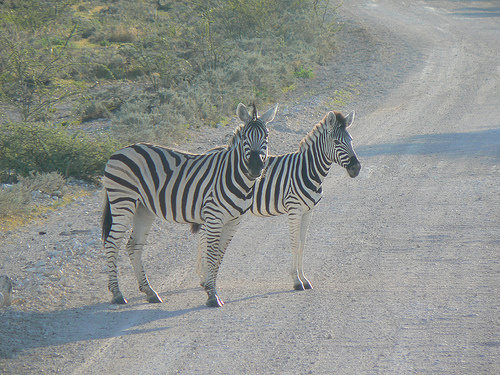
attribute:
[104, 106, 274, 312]
zebra — black, white, striped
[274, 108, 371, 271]
zebra — black, white, striped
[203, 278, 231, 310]
hoofs — black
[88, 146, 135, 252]
hind quarters — black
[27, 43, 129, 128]
leaves — green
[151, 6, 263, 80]
plants — green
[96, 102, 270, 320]
zebra — white, black, striped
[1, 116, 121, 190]
bush — green, small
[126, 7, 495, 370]
road — dirt, hard, rugged, rough